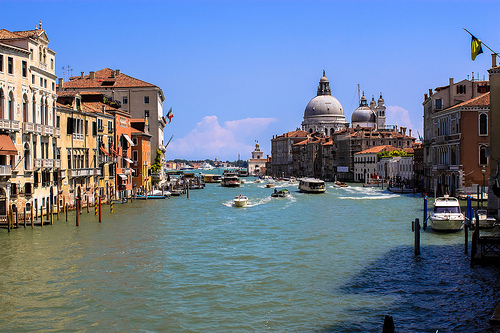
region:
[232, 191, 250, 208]
a white speed boat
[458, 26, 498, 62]
a long green and yellow flag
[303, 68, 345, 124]
an elegant dome roof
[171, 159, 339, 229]
a lot of boats on a river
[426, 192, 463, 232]
a docked white boat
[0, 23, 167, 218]
a row of buildings on the river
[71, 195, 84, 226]
a red pole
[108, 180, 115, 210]
a striped red pole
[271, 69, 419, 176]
a row of buildings on the river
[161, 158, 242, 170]
a row of distant buildings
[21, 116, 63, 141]
some balconys on one of the buildings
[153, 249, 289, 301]
a large body of water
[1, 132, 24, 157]
an awning over a balcony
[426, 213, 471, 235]
the front of a boat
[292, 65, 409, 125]
decorative top of a building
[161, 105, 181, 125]
an italian flag on a building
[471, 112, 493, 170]
two windows on a building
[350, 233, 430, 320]
a buildings shadow in the water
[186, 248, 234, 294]
ripples in the water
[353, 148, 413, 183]
a small white building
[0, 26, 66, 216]
this is a building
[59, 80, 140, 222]
this is a building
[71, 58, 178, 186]
this is a building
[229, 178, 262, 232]
this is a ship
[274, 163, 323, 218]
this is a ship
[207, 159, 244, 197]
this is a ship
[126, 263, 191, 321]
the water is calm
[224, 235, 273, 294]
the water is calm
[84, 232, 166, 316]
the water is calm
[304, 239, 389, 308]
the water is calm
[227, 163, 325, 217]
boats in canal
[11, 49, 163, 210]
buildings along canal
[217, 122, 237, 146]
white clouds in blue sky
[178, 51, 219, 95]
white clouds in blue sky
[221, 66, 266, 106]
white clouds in blue sky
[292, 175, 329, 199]
a boat in the ocean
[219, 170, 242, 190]
a boat in the ocean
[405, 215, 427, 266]
a pillar in the ocean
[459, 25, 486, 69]
a blue and yellow flag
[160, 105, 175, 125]
a red white and blue flag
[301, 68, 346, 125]
the dome of a building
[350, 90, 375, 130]
the dome of a building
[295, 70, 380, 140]
a group of domed building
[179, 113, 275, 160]
a cloud in the sky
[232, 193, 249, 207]
boat speeding down river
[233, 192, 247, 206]
yellow boat moving on the canal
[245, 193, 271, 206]
wake behind boat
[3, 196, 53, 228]
poles next to dock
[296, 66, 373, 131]
large dome to the left of small dome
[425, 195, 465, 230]
white boat is docked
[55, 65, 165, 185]
roof on top of stone building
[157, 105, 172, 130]
flags hanging from building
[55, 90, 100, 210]
building next to canal is yellow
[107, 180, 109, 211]
striped pole in front of building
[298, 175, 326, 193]
vaporetto floating on canal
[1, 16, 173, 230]
row of houses on waterfront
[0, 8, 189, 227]
row of houses on waterfront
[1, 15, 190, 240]
row of houses on waterfront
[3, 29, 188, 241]
row of houses on waterfront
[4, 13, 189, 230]
row of houses on waterfront